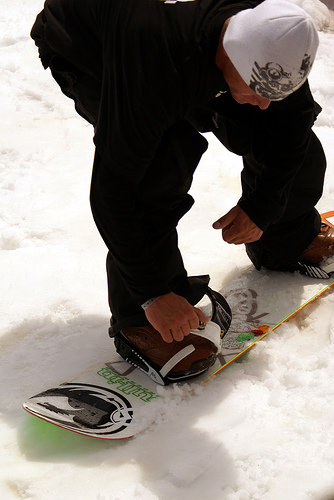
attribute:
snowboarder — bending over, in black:
[34, 3, 332, 365]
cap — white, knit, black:
[224, 2, 319, 102]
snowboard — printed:
[27, 204, 334, 441]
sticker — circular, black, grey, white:
[28, 384, 127, 434]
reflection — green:
[1, 311, 259, 499]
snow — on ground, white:
[3, 3, 329, 495]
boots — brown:
[125, 311, 214, 371]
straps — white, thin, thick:
[155, 330, 220, 375]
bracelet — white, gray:
[140, 289, 167, 316]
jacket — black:
[51, 1, 284, 229]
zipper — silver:
[210, 88, 224, 100]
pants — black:
[40, 20, 186, 321]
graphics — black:
[252, 51, 312, 96]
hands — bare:
[140, 208, 264, 344]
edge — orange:
[214, 280, 334, 376]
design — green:
[95, 330, 257, 402]